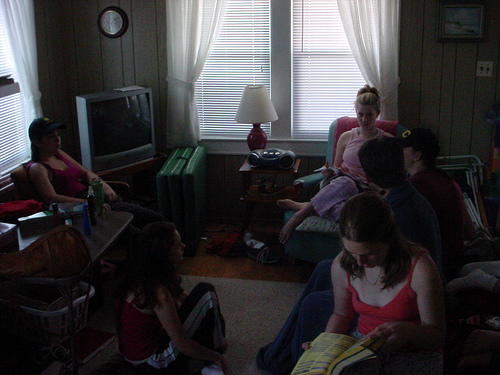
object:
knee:
[190, 279, 222, 323]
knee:
[330, 175, 359, 201]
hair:
[122, 208, 180, 304]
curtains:
[334, 0, 397, 122]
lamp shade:
[230, 81, 279, 124]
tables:
[157, 142, 213, 262]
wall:
[40, 0, 492, 232]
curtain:
[164, 0, 224, 145]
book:
[288, 330, 390, 373]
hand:
[368, 320, 405, 346]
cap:
[23, 113, 62, 147]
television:
[54, 80, 159, 180]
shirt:
[340, 120, 388, 182]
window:
[184, 0, 372, 142]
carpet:
[189, 275, 297, 371]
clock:
[97, 8, 126, 36]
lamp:
[229, 80, 282, 152]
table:
[237, 152, 307, 245]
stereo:
[242, 144, 299, 173]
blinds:
[194, 0, 359, 137]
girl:
[23, 115, 161, 247]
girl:
[270, 75, 400, 242]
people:
[355, 138, 475, 284]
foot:
[273, 207, 312, 245]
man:
[394, 123, 479, 283]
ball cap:
[396, 124, 441, 158]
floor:
[176, 229, 311, 281]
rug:
[80, 252, 308, 373]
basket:
[20, 272, 106, 350]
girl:
[101, 214, 241, 370]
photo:
[1, 1, 498, 373]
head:
[331, 193, 404, 272]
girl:
[300, 191, 443, 375]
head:
[25, 113, 65, 166]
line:
[414, 17, 425, 120]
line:
[440, 51, 442, 134]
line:
[468, 93, 478, 158]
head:
[121, 217, 201, 285]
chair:
[11, 165, 141, 226]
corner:
[31, 0, 183, 227]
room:
[0, 0, 498, 373]